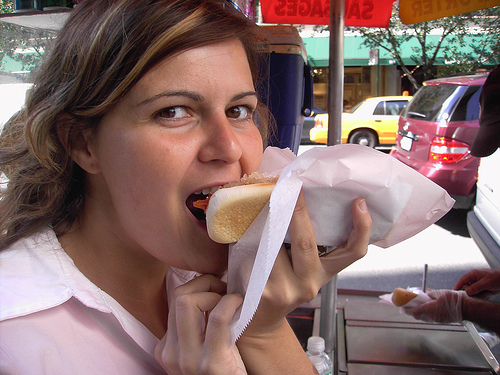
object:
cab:
[308, 87, 415, 150]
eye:
[154, 99, 196, 129]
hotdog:
[196, 165, 407, 245]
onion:
[220, 171, 282, 186]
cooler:
[248, 24, 317, 151]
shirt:
[1, 218, 223, 371]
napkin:
[214, 134, 456, 336]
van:
[382, 68, 490, 212]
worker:
[397, 63, 498, 348]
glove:
[403, 290, 466, 325]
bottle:
[299, 332, 337, 374]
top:
[306, 334, 326, 349]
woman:
[3, 0, 373, 375]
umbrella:
[227, 4, 498, 30]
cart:
[283, 283, 495, 371]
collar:
[0, 222, 180, 373]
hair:
[3, 5, 285, 255]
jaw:
[133, 207, 257, 276]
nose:
[195, 108, 244, 168]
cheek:
[103, 132, 199, 193]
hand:
[230, 184, 377, 317]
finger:
[318, 198, 371, 276]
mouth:
[185, 177, 242, 247]